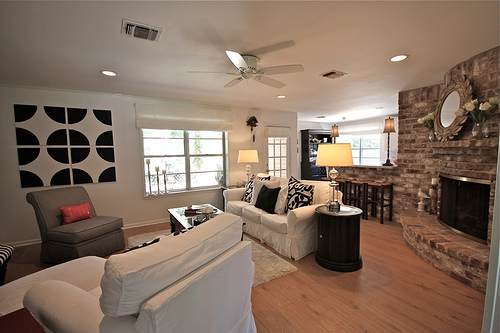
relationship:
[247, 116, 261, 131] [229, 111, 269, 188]
clock on wall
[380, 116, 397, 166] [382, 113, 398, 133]
table lamp with shade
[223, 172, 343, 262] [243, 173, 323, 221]
couch with pillows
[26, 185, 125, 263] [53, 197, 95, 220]
chair with red pillow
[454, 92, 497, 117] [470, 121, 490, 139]
white roses in vase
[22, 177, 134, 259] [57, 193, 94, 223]
chair with red pillow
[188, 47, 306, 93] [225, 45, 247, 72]
ceiling fan with blade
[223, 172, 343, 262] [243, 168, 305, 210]
couch with pillows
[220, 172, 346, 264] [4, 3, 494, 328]
couch in living room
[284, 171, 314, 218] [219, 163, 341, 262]
pillow on couch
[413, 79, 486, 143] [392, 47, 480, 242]
framed mirror on wall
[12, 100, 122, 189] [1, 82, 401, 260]
picture on wall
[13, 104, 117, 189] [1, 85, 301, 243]
picture on wall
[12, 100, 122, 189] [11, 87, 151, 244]
picture on wall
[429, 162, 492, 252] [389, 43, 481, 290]
fireplace in wall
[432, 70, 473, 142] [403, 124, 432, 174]
framed mirror on wall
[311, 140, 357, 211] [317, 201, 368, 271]
lamp on end table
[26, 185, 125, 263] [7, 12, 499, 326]
chair in room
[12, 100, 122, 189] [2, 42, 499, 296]
picture on wall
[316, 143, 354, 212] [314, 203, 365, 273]
lamp with end table